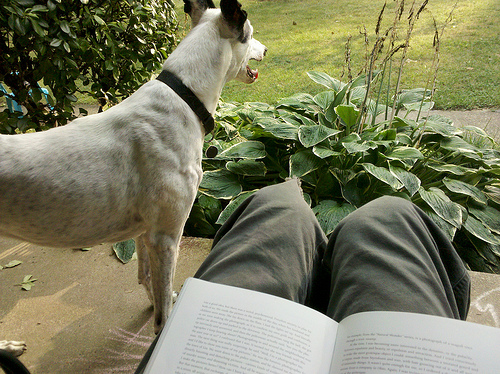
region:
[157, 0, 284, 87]
Dog alerting on something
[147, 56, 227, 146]
Collar worn by white dog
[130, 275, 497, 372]
Book in the lap of photographer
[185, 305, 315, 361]
Printed text in a book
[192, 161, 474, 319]
Knees of the photographer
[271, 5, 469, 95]
Large grassy field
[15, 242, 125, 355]
Concrete porch surface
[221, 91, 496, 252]
Leafy plant beside porch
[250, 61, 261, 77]
Canine teeth in a dog's mouth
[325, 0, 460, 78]
Weeds that look like wheat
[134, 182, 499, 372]
a person is sitting down with an open an open book on their lap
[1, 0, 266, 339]
white dog is standing looking out on the yard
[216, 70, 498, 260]
a green bush with dead flowers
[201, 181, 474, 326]
pants are a off green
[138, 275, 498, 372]
the book is laying open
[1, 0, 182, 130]
a taller green bush to the left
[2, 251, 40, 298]
there are leaves on the ground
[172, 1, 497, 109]
the lawn is green grass that is slightly brown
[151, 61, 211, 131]
the dog's color is black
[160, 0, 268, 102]
the dogs ears are pointed upwards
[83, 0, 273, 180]
a white dog with brown ears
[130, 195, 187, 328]
2 front legs of a dog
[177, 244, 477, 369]
an open book laying on a person's lap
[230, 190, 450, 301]
a person wearing gray pants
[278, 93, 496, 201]
green plants on the ground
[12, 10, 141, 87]
green shrubbery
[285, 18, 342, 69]
a shadow cast on the grass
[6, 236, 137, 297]
leaves on the ground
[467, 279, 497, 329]
A chalk mark on the ground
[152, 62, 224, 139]
a black dog collar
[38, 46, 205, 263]
dog is mostly white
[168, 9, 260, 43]
dog has brown ears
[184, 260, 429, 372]
person is reading book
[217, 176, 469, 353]
person wears green pants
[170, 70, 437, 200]
leafy plant in front of dog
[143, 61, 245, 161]
dog has black collar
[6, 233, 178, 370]
dog standing on concrete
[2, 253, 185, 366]
concrete is tan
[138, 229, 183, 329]
dog has white legs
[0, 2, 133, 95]
bush in front of dog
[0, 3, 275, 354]
Dog standing up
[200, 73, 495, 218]
Large green plant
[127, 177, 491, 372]
Person with an open book on their lap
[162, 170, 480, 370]
Two legs and a book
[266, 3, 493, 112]
Low cut green grass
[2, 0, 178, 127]
Large bush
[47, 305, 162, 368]
Chalk drawings on the concrete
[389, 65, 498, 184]
Concrete sidewalk by the yard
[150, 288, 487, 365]
Words on the pages of a book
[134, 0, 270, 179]
Collar around a dog's neck